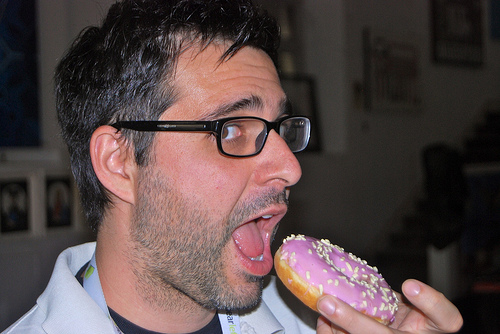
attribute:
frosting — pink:
[288, 233, 399, 317]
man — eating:
[60, 38, 323, 322]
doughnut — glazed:
[253, 223, 415, 316]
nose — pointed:
[254, 131, 304, 188]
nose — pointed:
[259, 135, 308, 195]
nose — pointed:
[254, 131, 303, 199]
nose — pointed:
[252, 127, 311, 189]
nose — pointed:
[253, 143, 310, 193]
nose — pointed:
[256, 139, 305, 191]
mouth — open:
[227, 198, 292, 282]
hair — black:
[55, 7, 282, 165]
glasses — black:
[86, 104, 324, 167]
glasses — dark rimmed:
[101, 109, 317, 161]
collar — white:
[8, 227, 331, 332]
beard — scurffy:
[130, 165, 288, 308]